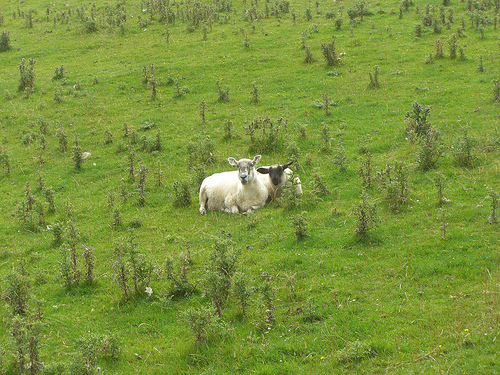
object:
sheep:
[199, 155, 268, 218]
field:
[2, 4, 500, 371]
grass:
[3, 3, 500, 375]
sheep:
[257, 162, 303, 208]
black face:
[269, 166, 283, 186]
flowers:
[81, 151, 91, 159]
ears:
[228, 157, 238, 166]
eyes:
[237, 165, 240, 169]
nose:
[240, 174, 247, 179]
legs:
[199, 188, 207, 208]